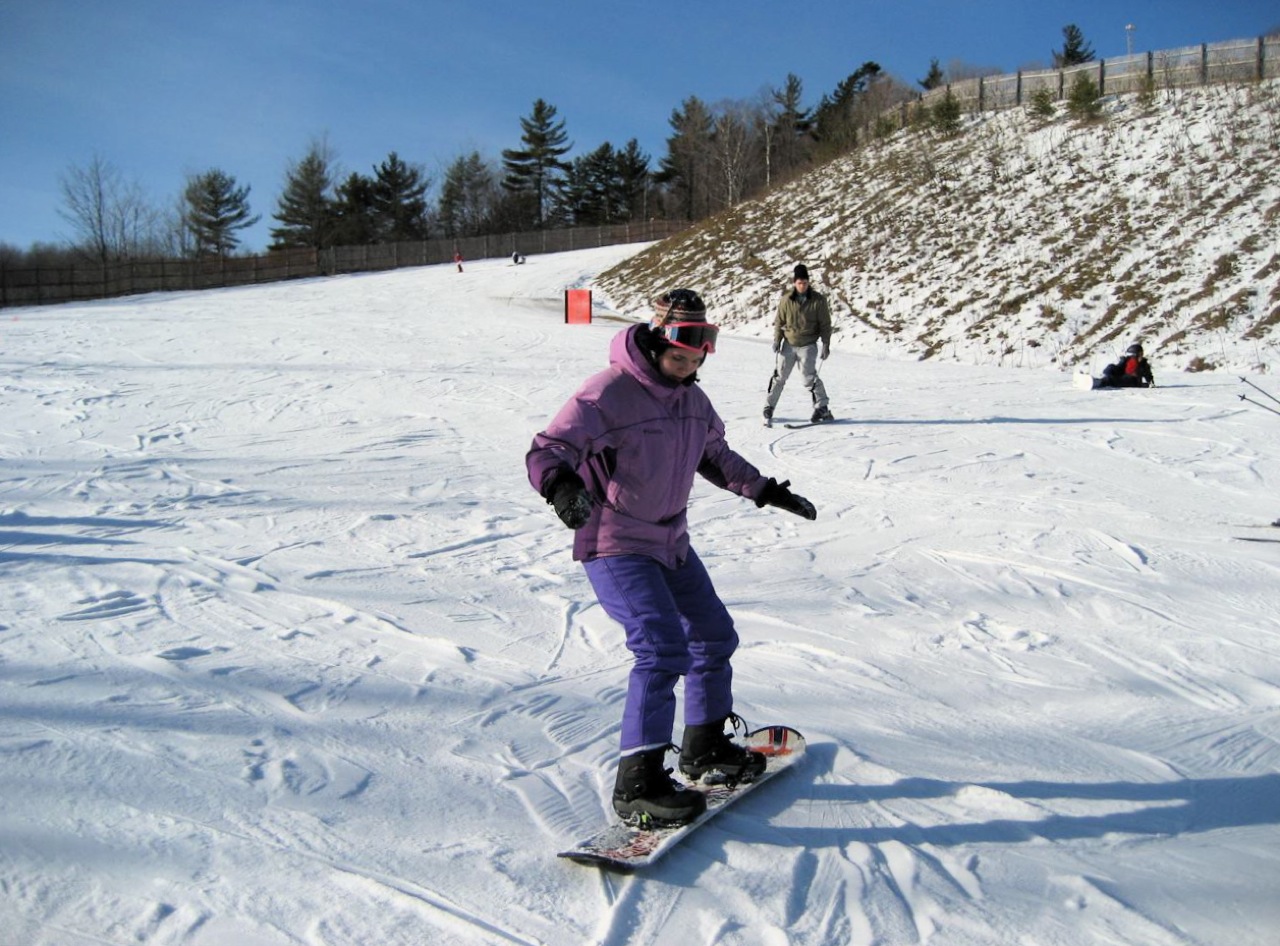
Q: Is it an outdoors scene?
A: Yes, it is outdoors.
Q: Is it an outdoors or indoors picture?
A: It is outdoors.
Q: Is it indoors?
A: No, it is outdoors.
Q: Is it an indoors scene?
A: No, it is outdoors.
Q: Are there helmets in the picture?
A: No, there are no helmets.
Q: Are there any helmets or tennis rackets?
A: No, there are no helmets or tennis rackets.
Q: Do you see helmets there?
A: No, there are no helmets.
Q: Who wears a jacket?
A: The man wears a jacket.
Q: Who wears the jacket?
A: The man wears a jacket.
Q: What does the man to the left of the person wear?
A: The man wears a jacket.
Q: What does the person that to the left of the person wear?
A: The man wears a jacket.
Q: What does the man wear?
A: The man wears a jacket.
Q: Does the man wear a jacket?
A: Yes, the man wears a jacket.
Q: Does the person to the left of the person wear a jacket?
A: Yes, the man wears a jacket.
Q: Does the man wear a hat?
A: No, the man wears a jacket.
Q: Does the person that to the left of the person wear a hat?
A: No, the man wears a jacket.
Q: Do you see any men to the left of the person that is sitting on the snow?
A: Yes, there is a man to the left of the person.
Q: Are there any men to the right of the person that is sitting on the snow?
A: No, the man is to the left of the person.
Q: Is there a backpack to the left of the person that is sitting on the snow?
A: No, there is a man to the left of the person.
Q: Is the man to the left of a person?
A: Yes, the man is to the left of a person.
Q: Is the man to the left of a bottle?
A: No, the man is to the left of a person.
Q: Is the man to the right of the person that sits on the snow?
A: No, the man is to the left of the person.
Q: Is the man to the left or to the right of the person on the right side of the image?
A: The man is to the left of the person.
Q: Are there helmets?
A: No, there are no helmets.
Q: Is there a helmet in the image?
A: No, there are no helmets.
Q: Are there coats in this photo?
A: Yes, there is a coat.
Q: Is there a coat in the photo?
A: Yes, there is a coat.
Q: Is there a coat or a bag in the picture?
A: Yes, there is a coat.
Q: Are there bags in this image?
A: No, there are no bags.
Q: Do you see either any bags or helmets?
A: No, there are no bags or helmets.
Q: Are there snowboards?
A: Yes, there is a snowboard.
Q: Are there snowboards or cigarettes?
A: Yes, there is a snowboard.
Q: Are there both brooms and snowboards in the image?
A: No, there is a snowboard but no brooms.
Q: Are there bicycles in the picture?
A: No, there are no bicycles.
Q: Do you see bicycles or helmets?
A: No, there are no bicycles or helmets.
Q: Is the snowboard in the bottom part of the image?
A: Yes, the snowboard is in the bottom of the image.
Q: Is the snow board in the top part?
A: No, the snow board is in the bottom of the image.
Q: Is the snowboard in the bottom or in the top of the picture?
A: The snowboard is in the bottom of the image.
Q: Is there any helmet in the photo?
A: No, there are no helmets.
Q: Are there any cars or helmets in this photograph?
A: No, there are no helmets or cars.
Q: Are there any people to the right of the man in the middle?
A: Yes, there is a person to the right of the man.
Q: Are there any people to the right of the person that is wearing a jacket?
A: Yes, there is a person to the right of the man.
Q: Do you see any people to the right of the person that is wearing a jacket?
A: Yes, there is a person to the right of the man.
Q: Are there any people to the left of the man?
A: No, the person is to the right of the man.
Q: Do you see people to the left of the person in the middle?
A: No, the person is to the right of the man.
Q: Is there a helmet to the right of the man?
A: No, there is a person to the right of the man.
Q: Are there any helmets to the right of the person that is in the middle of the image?
A: No, there is a person to the right of the man.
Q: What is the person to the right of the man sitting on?
A: The person is sitting on the snow.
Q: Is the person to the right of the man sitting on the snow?
A: Yes, the person is sitting on the snow.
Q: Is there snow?
A: Yes, there is snow.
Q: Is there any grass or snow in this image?
A: Yes, there is snow.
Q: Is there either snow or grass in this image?
A: Yes, there is snow.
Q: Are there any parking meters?
A: No, there are no parking meters.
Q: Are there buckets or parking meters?
A: No, there are no parking meters or buckets.